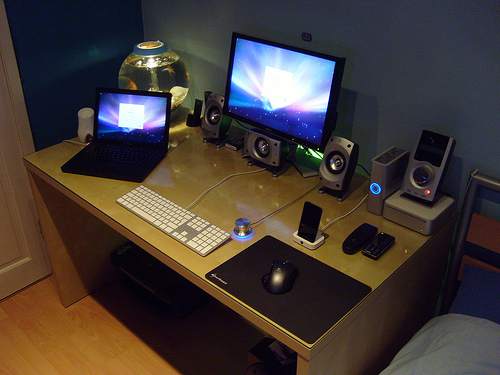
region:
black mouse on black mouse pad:
[202, 233, 373, 350]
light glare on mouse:
[271, 262, 288, 287]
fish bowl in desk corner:
[108, 35, 190, 125]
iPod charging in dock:
[289, 195, 330, 251]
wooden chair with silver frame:
[430, 163, 499, 325]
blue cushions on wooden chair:
[370, 256, 499, 371]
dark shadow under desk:
[63, 183, 310, 371]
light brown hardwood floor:
[0, 251, 301, 373]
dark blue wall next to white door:
[1, 2, 146, 152]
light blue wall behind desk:
[143, 0, 499, 312]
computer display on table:
[213, 30, 347, 146]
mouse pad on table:
[212, 231, 373, 348]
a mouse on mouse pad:
[257, 253, 300, 305]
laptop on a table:
[51, 69, 193, 199]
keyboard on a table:
[115, 175, 237, 265]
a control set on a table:
[230, 213, 263, 238]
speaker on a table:
[314, 131, 360, 195]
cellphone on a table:
[346, 214, 399, 264]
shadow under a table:
[83, 268, 210, 371]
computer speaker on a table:
[237, 128, 300, 182]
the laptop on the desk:
[71, 80, 168, 183]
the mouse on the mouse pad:
[265, 246, 290, 296]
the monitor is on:
[215, 15, 320, 155]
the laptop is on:
[80, 85, 170, 160]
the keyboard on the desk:
[95, 170, 230, 265]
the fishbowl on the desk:
[110, 30, 190, 101]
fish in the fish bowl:
[150, 65, 172, 75]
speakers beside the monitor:
[200, 96, 345, 188]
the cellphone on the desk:
[358, 227, 402, 260]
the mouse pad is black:
[211, 232, 378, 350]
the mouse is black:
[257, 255, 306, 297]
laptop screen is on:
[55, 75, 174, 191]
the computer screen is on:
[211, 25, 343, 156]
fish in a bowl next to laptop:
[98, 26, 215, 124]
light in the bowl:
[128, 47, 178, 71]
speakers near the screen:
[236, 124, 361, 201]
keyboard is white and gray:
[106, 174, 240, 267]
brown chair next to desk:
[444, 167, 499, 327]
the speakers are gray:
[198, 94, 365, 206]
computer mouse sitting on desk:
[258, 249, 299, 296]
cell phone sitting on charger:
[290, 197, 328, 251]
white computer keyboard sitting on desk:
[113, 181, 233, 256]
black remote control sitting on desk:
[341, 215, 379, 259]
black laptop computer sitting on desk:
[58, 81, 175, 186]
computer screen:
[216, 26, 347, 157]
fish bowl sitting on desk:
[111, 35, 192, 119]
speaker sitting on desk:
[309, 130, 360, 205]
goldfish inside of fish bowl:
[117, 68, 140, 92]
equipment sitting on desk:
[363, 123, 460, 238]